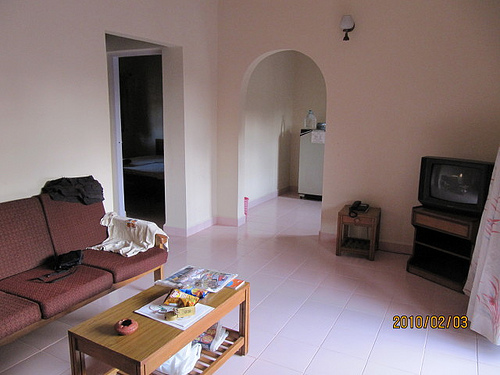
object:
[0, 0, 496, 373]
living room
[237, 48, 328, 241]
archway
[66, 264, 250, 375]
coffee table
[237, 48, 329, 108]
archway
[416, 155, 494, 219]
tv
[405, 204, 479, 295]
stand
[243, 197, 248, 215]
wastebasket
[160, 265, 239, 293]
newspaper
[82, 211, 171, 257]
shirt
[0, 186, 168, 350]
couch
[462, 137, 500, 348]
drapes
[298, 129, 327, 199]
refrigerator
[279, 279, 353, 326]
tile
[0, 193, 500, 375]
floor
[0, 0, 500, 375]
living room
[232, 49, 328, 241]
doorway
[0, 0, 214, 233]
wall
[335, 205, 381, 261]
small table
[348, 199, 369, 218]
telephone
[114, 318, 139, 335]
ashtray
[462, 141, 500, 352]
curtains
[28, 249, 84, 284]
purse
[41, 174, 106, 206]
pants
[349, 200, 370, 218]
phone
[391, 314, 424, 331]
year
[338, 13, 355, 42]
light